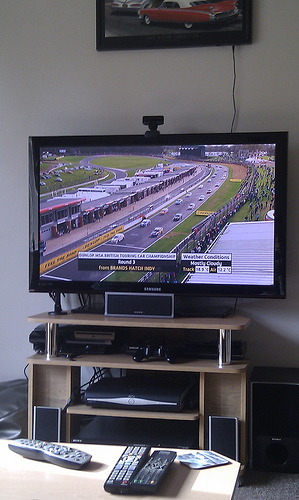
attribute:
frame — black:
[28, 133, 288, 296]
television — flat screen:
[27, 115, 288, 301]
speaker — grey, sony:
[103, 290, 177, 318]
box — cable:
[85, 377, 192, 410]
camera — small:
[143, 114, 164, 136]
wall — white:
[0, 1, 298, 383]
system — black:
[30, 328, 126, 358]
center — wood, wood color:
[26, 312, 252, 487]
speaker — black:
[249, 369, 298, 477]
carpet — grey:
[234, 468, 298, 499]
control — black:
[130, 449, 177, 493]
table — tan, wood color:
[0, 438, 246, 499]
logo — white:
[142, 285, 165, 293]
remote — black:
[8, 437, 91, 471]